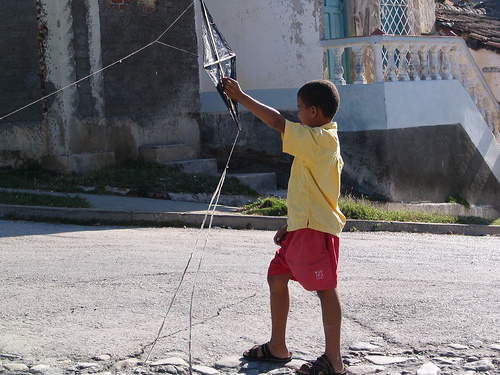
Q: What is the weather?
A: Sunny.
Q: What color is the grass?
A: Green.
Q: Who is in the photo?
A: A boy.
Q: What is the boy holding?
A: A kite.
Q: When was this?
A: Daytime.